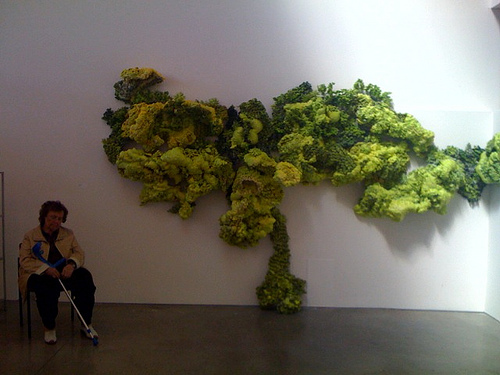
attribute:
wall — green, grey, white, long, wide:
[2, 4, 500, 301]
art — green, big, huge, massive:
[105, 67, 494, 311]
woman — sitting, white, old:
[11, 191, 111, 348]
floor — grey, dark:
[4, 290, 492, 375]